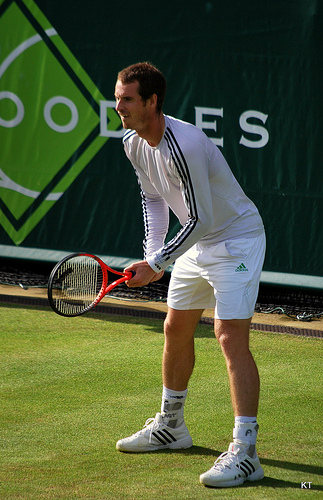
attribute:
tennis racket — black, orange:
[34, 227, 118, 331]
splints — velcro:
[160, 383, 260, 426]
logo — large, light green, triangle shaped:
[233, 263, 248, 269]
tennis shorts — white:
[155, 251, 260, 317]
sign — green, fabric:
[9, 26, 121, 179]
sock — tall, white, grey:
[153, 380, 188, 429]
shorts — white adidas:
[165, 230, 266, 317]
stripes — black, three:
[126, 422, 258, 475]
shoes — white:
[118, 410, 265, 481]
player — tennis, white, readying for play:
[114, 59, 271, 489]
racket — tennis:
[45, 251, 138, 317]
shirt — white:
[111, 61, 268, 491]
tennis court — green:
[0, 293, 322, 499]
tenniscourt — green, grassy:
[1, 304, 319, 498]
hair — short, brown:
[116, 62, 165, 121]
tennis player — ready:
[111, 62, 266, 487]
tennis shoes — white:
[200, 445, 278, 488]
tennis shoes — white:
[110, 412, 199, 453]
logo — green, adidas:
[236, 261, 252, 273]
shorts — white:
[161, 228, 269, 321]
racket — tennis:
[38, 236, 167, 314]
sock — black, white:
[225, 419, 257, 445]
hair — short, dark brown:
[104, 57, 180, 109]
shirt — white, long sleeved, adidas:
[114, 117, 265, 267]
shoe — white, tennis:
[194, 438, 277, 495]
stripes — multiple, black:
[157, 133, 207, 231]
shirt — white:
[112, 121, 255, 238]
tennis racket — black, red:
[43, 251, 136, 318]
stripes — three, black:
[141, 133, 214, 268]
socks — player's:
[148, 385, 279, 460]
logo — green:
[229, 258, 256, 275]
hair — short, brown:
[114, 59, 177, 119]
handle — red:
[86, 255, 145, 300]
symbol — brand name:
[235, 255, 250, 276]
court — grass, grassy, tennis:
[5, 296, 315, 499]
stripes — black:
[183, 225, 192, 246]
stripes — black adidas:
[245, 446, 250, 482]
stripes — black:
[167, 224, 195, 255]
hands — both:
[115, 250, 163, 289]